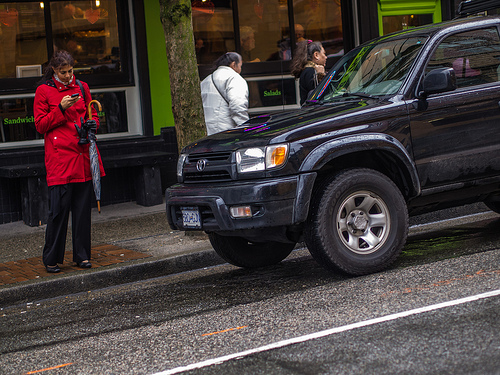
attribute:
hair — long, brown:
[293, 35, 323, 70]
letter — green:
[15, 114, 21, 124]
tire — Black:
[285, 149, 428, 295]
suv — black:
[162, 21, 482, 273]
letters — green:
[4, 110, 34, 130]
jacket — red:
[31, 77, 114, 187]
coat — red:
[30, 77, 107, 186]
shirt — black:
[29, 83, 125, 182]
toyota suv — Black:
[164, 12, 499, 278]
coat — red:
[31, 69, 112, 191]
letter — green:
[184, 211, 195, 224]